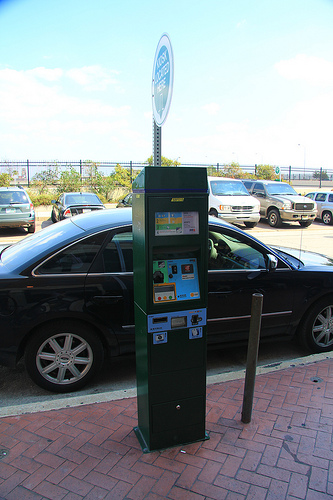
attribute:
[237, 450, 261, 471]
bricks — red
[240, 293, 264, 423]
pole — metal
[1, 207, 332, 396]
car — reflective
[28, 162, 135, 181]
fence — metal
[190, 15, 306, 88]
sky — clear, white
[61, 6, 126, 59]
sky — clear, white